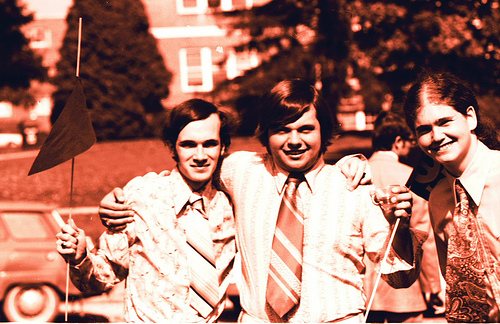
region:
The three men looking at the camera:
[60, 73, 497, 318]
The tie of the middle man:
[260, 170, 305, 315]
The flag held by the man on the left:
[25, 17, 100, 320]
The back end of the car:
[0, 200, 116, 320]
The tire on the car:
[2, 280, 62, 320]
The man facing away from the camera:
[355, 107, 445, 318]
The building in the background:
[0, 0, 386, 140]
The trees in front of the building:
[1, 0, 496, 155]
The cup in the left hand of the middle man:
[365, 175, 410, 225]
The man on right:
[381, 57, 497, 319]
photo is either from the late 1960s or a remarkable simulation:
[0, 1, 498, 322]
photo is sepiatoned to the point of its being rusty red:
[0, 0, 498, 322]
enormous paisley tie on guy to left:
[438, 179, 498, 321]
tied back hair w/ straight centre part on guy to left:
[395, 68, 498, 150]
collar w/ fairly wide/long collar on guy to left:
[428, 138, 494, 218]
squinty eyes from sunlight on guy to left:
[415, 113, 452, 136]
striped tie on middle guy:
[259, 168, 309, 322]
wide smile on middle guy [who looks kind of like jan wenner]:
[275, 143, 310, 160]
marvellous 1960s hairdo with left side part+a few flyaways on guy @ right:
[155, 93, 231, 183]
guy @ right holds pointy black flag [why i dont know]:
[23, 11, 98, 321]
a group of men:
[49, 26, 460, 313]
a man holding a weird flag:
[61, 88, 246, 319]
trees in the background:
[61, 6, 495, 106]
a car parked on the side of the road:
[18, 186, 83, 313]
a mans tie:
[269, 172, 318, 320]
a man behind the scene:
[344, 96, 431, 188]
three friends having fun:
[36, 74, 491, 313]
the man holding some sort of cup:
[338, 160, 453, 238]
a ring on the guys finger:
[59, 243, 86, 256]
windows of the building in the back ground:
[169, 20, 249, 100]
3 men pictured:
[87, 50, 497, 301]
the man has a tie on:
[260, 180, 313, 311]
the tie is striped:
[261, 170, 319, 311]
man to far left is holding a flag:
[35, 56, 235, 296]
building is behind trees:
[140, 0, 281, 98]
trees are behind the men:
[45, 10, 491, 188]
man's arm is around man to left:
[90, 153, 340, 246]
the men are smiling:
[50, 98, 481, 249]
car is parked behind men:
[0, 208, 90, 314]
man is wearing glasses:
[378, 121, 421, 159]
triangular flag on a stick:
[16, 12, 109, 216]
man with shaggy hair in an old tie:
[105, 95, 247, 317]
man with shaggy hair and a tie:
[225, 58, 365, 322]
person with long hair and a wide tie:
[386, 62, 496, 316]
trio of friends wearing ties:
[103, 63, 498, 243]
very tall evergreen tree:
[53, 7, 167, 145]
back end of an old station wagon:
[8, 194, 63, 314]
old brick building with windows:
[153, 10, 223, 92]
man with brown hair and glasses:
[358, 102, 424, 182]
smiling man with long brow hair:
[399, 62, 488, 177]